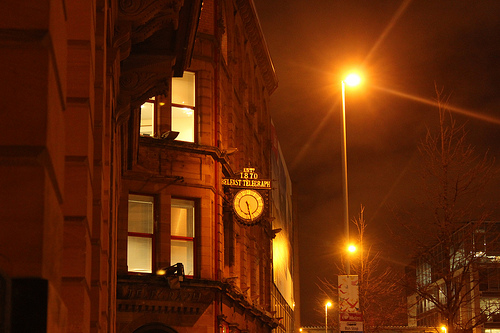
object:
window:
[126, 188, 200, 279]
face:
[232, 189, 265, 222]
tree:
[315, 204, 420, 333]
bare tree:
[315, 202, 410, 332]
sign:
[335, 273, 365, 333]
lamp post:
[337, 73, 351, 274]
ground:
[0, 312, 500, 333]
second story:
[115, 14, 296, 217]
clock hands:
[243, 200, 254, 224]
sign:
[220, 167, 275, 190]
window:
[137, 63, 201, 145]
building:
[0, 0, 302, 333]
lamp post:
[324, 292, 329, 329]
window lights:
[157, 261, 184, 290]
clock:
[228, 187, 270, 226]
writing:
[338, 312, 361, 319]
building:
[402, 215, 500, 333]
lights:
[340, 66, 363, 90]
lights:
[344, 242, 357, 256]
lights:
[323, 300, 333, 309]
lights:
[436, 322, 447, 333]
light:
[173, 209, 184, 237]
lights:
[171, 97, 194, 114]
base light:
[0, 158, 500, 333]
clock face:
[231, 188, 265, 222]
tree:
[383, 79, 499, 333]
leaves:
[365, 205, 444, 255]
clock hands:
[245, 201, 253, 221]